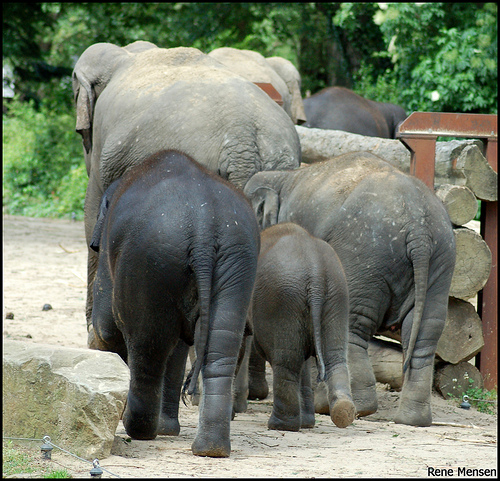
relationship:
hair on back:
[128, 145, 217, 189] [129, 172, 263, 220]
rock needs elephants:
[33, 342, 141, 399] [133, 25, 404, 425]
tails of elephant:
[174, 289, 238, 373] [109, 199, 254, 406]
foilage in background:
[379, 23, 467, 88] [126, 2, 495, 62]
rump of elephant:
[134, 231, 280, 305] [109, 199, 254, 406]